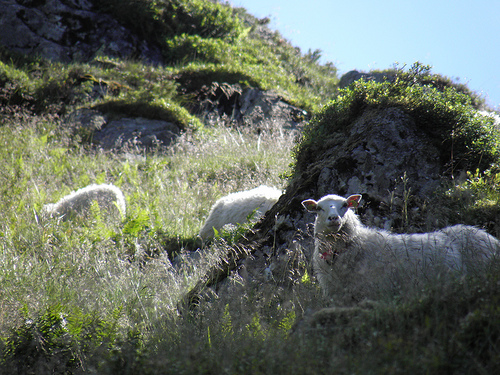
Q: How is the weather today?
A: It is clear.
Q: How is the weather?
A: It is clear.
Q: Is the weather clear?
A: Yes, it is clear.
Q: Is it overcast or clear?
A: It is clear.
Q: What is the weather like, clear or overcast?
A: It is clear.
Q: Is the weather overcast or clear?
A: It is clear.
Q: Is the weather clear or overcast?
A: It is clear.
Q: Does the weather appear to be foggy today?
A: No, it is clear.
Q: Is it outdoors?
A: Yes, it is outdoors.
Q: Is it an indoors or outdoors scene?
A: It is outdoors.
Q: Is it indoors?
A: No, it is outdoors.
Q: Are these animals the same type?
A: Yes, all the animals are sheep.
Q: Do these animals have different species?
A: No, all the animals are sheep.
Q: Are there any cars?
A: No, there are no cars.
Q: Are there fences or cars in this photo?
A: No, there are no cars or fences.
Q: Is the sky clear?
A: Yes, the sky is clear.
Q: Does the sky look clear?
A: Yes, the sky is clear.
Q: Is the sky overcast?
A: No, the sky is clear.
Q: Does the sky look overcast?
A: No, the sky is clear.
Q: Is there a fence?
A: No, there are no fences.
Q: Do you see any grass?
A: Yes, there is grass.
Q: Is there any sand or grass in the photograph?
A: Yes, there is grass.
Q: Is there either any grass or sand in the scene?
A: Yes, there is grass.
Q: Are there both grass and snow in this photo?
A: No, there is grass but no snow.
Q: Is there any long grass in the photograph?
A: Yes, there is long grass.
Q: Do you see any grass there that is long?
A: Yes, there is grass that is long.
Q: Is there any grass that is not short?
A: Yes, there is long grass.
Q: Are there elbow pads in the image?
A: No, there are no elbow pads.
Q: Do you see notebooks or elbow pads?
A: No, there are no elbow pads or notebooks.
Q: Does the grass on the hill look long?
A: Yes, the grass is long.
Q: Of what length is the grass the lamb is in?
A: The grass is long.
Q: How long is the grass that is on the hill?
A: The grass is long.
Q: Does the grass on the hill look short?
A: No, the grass is long.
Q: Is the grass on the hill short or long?
A: The grass is long.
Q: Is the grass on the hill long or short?
A: The grass is long.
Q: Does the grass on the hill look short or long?
A: The grass is long.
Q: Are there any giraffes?
A: No, there are no giraffes.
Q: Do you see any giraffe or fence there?
A: No, there are no giraffes or fences.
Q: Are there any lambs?
A: Yes, there is a lamb.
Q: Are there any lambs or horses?
A: Yes, there is a lamb.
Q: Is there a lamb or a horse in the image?
A: Yes, there is a lamb.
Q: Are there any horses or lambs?
A: Yes, there is a lamb.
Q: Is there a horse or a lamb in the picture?
A: Yes, there is a lamb.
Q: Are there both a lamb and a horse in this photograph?
A: No, there is a lamb but no horses.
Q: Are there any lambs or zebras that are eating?
A: Yes, the lamb is eating.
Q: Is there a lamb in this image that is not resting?
A: Yes, there is a lamb that is eating.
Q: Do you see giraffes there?
A: No, there are no giraffes.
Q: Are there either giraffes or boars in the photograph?
A: No, there are no giraffes or boars.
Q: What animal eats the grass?
A: The lamb eats the grass.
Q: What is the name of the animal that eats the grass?
A: The animal is a lamb.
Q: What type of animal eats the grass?
A: The animal is a lamb.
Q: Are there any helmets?
A: No, there are no helmets.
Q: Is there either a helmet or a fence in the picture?
A: No, there are no helmets or fences.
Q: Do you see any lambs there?
A: Yes, there is a lamb.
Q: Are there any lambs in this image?
A: Yes, there is a lamb.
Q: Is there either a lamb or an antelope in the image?
A: Yes, there is a lamb.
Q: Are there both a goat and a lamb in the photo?
A: No, there is a lamb but no goats.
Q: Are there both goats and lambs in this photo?
A: No, there is a lamb but no goats.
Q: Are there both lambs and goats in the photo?
A: No, there is a lamb but no goats.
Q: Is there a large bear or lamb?
A: Yes, there is a large lamb.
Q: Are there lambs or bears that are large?
A: Yes, the lamb is large.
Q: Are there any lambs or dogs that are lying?
A: Yes, the lamb is lying.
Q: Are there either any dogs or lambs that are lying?
A: Yes, the lamb is lying.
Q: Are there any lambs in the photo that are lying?
A: Yes, there is a lamb that is lying.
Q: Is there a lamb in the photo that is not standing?
A: Yes, there is a lamb that is lying.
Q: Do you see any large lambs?
A: Yes, there is a large lamb.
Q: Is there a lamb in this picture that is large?
A: Yes, there is a lamb that is large.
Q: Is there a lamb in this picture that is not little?
A: Yes, there is a large lamb.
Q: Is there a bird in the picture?
A: No, there are no birds.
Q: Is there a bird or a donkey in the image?
A: No, there are no birds or donkeys.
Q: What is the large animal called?
A: The animal is a lamb.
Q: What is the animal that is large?
A: The animal is a lamb.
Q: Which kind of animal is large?
A: The animal is a lamb.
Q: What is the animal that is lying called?
A: The animal is a lamb.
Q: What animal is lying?
A: The animal is a lamb.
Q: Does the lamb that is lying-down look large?
A: Yes, the lamb is large.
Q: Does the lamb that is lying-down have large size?
A: Yes, the lamb is large.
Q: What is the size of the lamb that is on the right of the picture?
A: The lamb is large.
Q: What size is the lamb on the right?
A: The lamb is large.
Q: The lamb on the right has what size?
A: The lamb is large.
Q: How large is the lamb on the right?
A: The lamb is large.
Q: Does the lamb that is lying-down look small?
A: No, the lamb is large.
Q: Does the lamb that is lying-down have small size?
A: No, the lamb is large.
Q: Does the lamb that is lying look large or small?
A: The lamb is large.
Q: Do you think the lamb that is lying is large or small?
A: The lamb is large.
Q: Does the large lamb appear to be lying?
A: Yes, the lamb is lying.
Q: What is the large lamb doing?
A: The lamb is lying.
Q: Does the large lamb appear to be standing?
A: No, the lamb is lying.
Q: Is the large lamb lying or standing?
A: The lamb is lying.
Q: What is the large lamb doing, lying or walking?
A: The lamb is lying.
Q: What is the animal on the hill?
A: The animal is a lamb.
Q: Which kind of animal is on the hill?
A: The animal is a lamb.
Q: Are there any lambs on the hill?
A: Yes, there is a lamb on the hill.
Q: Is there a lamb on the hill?
A: Yes, there is a lamb on the hill.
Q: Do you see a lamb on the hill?
A: Yes, there is a lamb on the hill.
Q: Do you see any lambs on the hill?
A: Yes, there is a lamb on the hill.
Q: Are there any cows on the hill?
A: No, there is a lamb on the hill.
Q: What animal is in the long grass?
A: The animal is a lamb.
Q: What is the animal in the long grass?
A: The animal is a lamb.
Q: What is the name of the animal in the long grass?
A: The animal is a lamb.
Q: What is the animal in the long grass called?
A: The animal is a lamb.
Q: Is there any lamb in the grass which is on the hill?
A: Yes, there is a lamb in the grass.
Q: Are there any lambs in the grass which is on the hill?
A: Yes, there is a lamb in the grass.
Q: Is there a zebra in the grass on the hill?
A: No, there is a lamb in the grass.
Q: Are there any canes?
A: No, there are no canes.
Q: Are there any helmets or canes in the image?
A: No, there are no canes or helmets.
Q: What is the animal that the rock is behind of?
A: The animal is a lamb.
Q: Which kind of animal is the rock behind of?
A: The rock is behind the lamb.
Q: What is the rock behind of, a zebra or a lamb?
A: The rock is behind a lamb.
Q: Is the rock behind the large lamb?
A: Yes, the rock is behind the lamb.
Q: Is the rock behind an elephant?
A: No, the rock is behind the lamb.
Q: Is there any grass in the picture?
A: Yes, there is grass.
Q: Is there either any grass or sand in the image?
A: Yes, there is grass.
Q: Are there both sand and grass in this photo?
A: No, there is grass but no sand.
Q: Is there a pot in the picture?
A: No, there are no pots.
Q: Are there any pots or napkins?
A: No, there are no pots or napkins.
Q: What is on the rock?
A: The grass is on the rock.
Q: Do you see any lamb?
A: Yes, there is a lamb.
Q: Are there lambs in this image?
A: Yes, there is a lamb.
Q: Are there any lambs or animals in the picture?
A: Yes, there is a lamb.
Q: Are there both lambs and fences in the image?
A: No, there is a lamb but no fences.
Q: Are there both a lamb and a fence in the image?
A: No, there is a lamb but no fences.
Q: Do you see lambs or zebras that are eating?
A: Yes, the lamb is eating.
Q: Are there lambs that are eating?
A: Yes, there is a lamb that is eating.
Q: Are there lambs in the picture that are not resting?
A: Yes, there is a lamb that is eating.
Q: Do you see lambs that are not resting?
A: Yes, there is a lamb that is eating .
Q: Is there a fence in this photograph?
A: No, there are no fences.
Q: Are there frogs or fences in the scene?
A: No, there are no fences or frogs.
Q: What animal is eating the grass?
A: The animal is a lamb.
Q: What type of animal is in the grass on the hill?
A: The animal is a lamb.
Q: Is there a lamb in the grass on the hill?
A: Yes, there is a lamb in the grass.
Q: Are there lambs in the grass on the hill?
A: Yes, there is a lamb in the grass.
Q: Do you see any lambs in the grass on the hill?
A: Yes, there is a lamb in the grass.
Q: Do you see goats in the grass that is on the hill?
A: No, there is a lamb in the grass.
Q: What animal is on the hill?
A: The animal is a lamb.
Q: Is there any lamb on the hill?
A: Yes, there is a lamb on the hill.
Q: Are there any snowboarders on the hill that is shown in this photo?
A: No, there is a lamb on the hill.